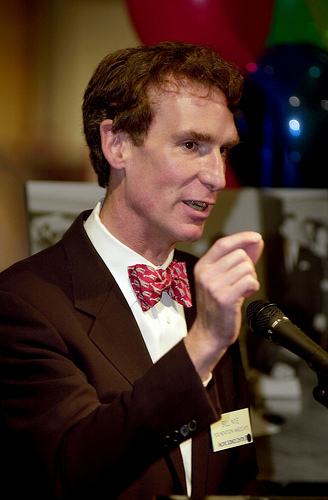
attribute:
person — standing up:
[9, 11, 327, 351]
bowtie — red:
[126, 256, 195, 311]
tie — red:
[124, 254, 197, 314]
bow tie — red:
[129, 263, 192, 307]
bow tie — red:
[120, 257, 195, 314]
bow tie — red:
[128, 257, 202, 324]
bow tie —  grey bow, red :
[124, 249, 201, 309]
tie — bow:
[121, 253, 196, 310]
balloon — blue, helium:
[221, 35, 327, 196]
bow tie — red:
[128, 258, 192, 310]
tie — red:
[93, 231, 251, 342]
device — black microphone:
[245, 293, 316, 378]